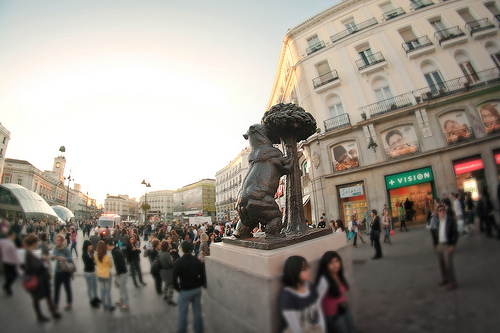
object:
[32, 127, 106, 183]
white clouds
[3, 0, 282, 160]
sky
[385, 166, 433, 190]
sign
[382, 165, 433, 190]
light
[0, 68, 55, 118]
clouds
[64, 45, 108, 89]
clouds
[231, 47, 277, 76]
clouds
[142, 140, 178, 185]
clouds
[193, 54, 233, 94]
clouds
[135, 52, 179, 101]
clouds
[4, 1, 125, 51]
cloud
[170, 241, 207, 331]
person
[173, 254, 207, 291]
black jacket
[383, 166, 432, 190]
green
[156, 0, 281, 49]
cloud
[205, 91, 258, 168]
clouds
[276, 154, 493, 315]
marketplace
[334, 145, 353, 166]
face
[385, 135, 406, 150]
face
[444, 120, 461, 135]
face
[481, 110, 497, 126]
face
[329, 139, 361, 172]
portrait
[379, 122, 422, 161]
portrait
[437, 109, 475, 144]
portrait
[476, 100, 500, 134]
portrait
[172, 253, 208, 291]
sweater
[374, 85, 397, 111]
window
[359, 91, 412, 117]
balcony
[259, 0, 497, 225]
building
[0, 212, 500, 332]
ground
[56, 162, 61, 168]
clock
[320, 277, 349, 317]
pink shirt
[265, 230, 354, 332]
wall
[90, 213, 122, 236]
truck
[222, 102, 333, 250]
statue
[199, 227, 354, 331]
platform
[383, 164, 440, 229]
store front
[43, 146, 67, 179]
tower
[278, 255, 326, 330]
woman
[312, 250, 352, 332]
woman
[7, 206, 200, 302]
crowd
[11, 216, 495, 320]
walkway